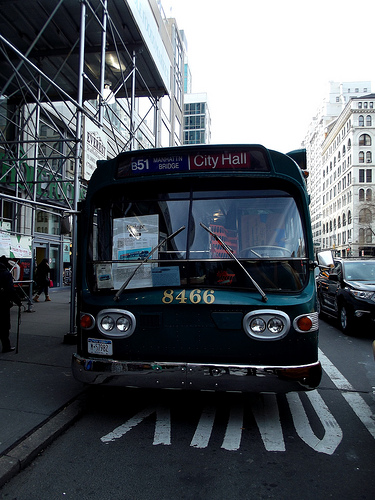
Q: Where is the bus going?
A: City Hall.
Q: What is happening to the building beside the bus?
A: Under construction.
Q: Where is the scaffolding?
A: On the sidewalk by the bus.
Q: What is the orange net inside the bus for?
A: To protect the driver.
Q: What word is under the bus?
A: Only.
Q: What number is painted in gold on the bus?
A: 8466.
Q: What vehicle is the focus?
A: Bus.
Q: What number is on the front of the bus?
A: 8466.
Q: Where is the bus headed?
A: City hall.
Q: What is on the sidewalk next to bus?
A: Scaffolding.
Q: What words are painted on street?
A: Only.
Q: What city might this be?
A: New york.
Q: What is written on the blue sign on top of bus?
A: Manhattan bridge.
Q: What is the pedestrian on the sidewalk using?
A: Cane.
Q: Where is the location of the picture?
A: A big city.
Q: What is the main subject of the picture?
A: A bus.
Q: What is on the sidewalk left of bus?
A: Scaffolding.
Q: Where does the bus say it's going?
A: City Hall.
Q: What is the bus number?
A: 8466.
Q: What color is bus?
A: Green.